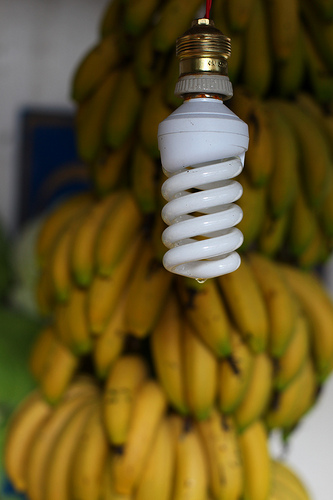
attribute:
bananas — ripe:
[14, 187, 332, 453]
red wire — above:
[200, 0, 213, 19]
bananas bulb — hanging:
[54, 209, 301, 423]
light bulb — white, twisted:
[153, 91, 250, 285]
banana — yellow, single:
[45, 243, 143, 433]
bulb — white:
[153, 71, 251, 281]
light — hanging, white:
[146, 22, 247, 283]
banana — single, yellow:
[197, 403, 243, 498]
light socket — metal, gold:
[175, 17, 230, 76]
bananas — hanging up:
[41, 7, 328, 211]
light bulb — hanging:
[158, 21, 246, 281]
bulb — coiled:
[151, 55, 262, 301]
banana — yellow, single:
[49, 206, 97, 307]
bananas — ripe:
[12, 6, 329, 497]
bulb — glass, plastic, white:
[158, 98, 248, 279]